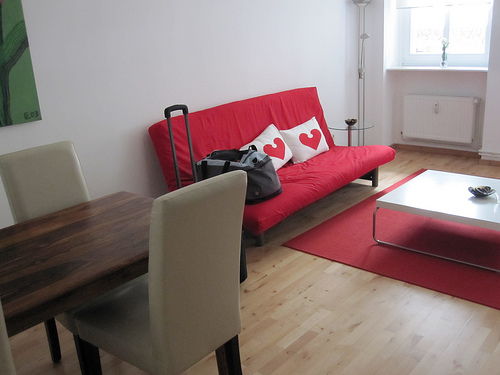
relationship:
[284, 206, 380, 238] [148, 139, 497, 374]
shadow on floor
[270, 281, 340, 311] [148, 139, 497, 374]
lines on wood floor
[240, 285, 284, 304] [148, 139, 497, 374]
small spots on floor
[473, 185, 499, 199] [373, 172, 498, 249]
ash tray on top of table top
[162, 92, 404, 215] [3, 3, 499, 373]
empty sofa in room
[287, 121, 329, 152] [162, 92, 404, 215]
pillow on sofa bed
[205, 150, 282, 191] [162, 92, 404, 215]
bag on sofa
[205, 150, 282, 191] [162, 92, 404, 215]
bag on top of sofa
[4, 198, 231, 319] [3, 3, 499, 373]
table in room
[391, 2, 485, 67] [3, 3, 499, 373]
window in room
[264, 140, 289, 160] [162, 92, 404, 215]
red heart on couch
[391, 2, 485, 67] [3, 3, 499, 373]
big window in room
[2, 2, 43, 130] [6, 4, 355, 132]
painting on wall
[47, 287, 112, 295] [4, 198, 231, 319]
edge of table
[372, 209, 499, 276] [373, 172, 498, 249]
stand of table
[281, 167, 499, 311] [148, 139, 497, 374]
carpet on floor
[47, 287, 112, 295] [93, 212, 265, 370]
edge of chair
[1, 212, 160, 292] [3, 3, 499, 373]
top of table in room